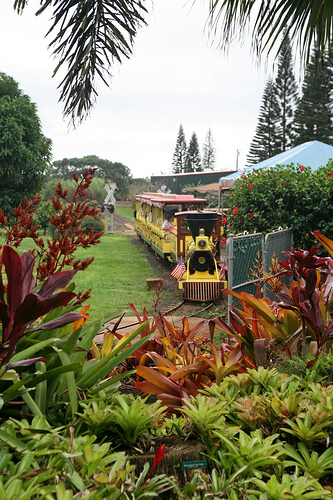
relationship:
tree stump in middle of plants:
[124, 440, 212, 489] [0, 165, 332, 500]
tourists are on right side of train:
[139, 203, 182, 245] [132, 193, 179, 258]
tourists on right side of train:
[139, 203, 182, 245] [132, 189, 230, 306]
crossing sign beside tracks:
[100, 182, 119, 207] [107, 208, 134, 232]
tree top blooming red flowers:
[220, 155, 331, 254] [217, 161, 331, 242]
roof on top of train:
[134, 190, 209, 208] [132, 189, 230, 306]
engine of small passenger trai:
[175, 210, 229, 302] [132, 189, 230, 306]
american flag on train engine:
[169, 251, 187, 283] [175, 210, 229, 302]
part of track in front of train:
[157, 299, 216, 325] [132, 189, 230, 306]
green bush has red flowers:
[220, 155, 331, 254] [217, 161, 331, 242]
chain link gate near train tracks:
[226, 226, 296, 341] [157, 299, 216, 325]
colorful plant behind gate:
[220, 155, 331, 254] [226, 226, 296, 341]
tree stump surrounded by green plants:
[124, 440, 212, 489] [0, 314, 331, 499]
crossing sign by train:
[100, 182, 119, 207] [132, 189, 230, 306]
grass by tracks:
[0, 233, 161, 329] [157, 299, 216, 325]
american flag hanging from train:
[169, 251, 187, 283] [132, 189, 230, 306]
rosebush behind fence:
[220, 155, 331, 254] [226, 226, 296, 341]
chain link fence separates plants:
[226, 226, 296, 341] [0, 165, 332, 500]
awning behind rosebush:
[217, 139, 331, 194] [220, 155, 331, 254]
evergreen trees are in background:
[169, 118, 219, 175] [0, 0, 331, 180]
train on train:
[132, 189, 230, 306] [133, 189, 229, 303]